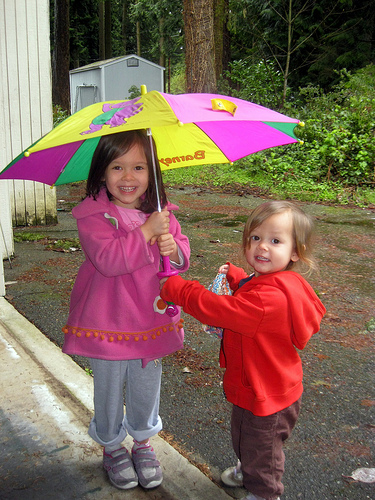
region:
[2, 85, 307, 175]
multi colored umbrella held by young girl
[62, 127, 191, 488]
young girl holding umbrella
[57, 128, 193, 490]
young girl wearing pink coat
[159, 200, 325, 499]
toddler helping hold umbrella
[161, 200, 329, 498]
toddler wearing red hooded jacket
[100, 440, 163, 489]
young girl's athletic shoes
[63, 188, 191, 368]
pink coat with orange ball fringe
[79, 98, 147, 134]
picture of Barney the dinosaur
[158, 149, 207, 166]
Barney the dinosaur's name on umbrella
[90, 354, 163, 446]
rolled up pants worn by young girl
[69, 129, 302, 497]
two kids smiling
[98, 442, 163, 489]
a couple of girl sneakers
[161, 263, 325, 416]
the long sleeve sweater is red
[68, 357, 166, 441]
the pant is gray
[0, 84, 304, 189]
an umbrella of barney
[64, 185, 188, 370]
a pink long sleeve sweater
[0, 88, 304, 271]
the girl holding the umbrella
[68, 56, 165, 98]
a white small house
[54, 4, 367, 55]
a dense forest in the background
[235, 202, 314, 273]
the head of the kid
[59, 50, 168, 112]
a storage shed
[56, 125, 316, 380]
two young children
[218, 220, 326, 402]
a young child wearing a red sweat shirt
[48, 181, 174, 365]
a young girl wearing a pink coat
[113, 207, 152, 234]
a young girl wearing a pink shirt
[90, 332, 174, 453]
a young girl wearing grey pants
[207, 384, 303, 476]
a young child wearing brown pants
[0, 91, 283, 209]
a yellow,purple and green umbrella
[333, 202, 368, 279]
green moss on the pavement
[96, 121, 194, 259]
a girl holding a umbrella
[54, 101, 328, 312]
two young children holding a umbrella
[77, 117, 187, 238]
a young girl with brown hair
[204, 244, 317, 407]
a young child wearing a red sweatshirt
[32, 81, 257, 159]
a purple and yellow umbrella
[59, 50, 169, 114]
a small shed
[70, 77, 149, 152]
a umbrella with a cartoon character on it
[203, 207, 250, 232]
green moss on the pavement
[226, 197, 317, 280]
a child with short hair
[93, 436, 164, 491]
Sneakers on the sidewalk.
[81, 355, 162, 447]
Little girl wearing grey pants.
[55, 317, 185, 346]
Small orange pom poms trim the coat.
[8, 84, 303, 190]
Barney on the umbrella.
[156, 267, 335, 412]
Wearing a red sweatshirt.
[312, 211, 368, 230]
Puddles on the ground.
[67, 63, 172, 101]
Shed in the background.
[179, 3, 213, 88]
Large tree trunk across the road.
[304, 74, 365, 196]
Leafy green trees next to the road.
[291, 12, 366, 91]
Pine tree in the distance.